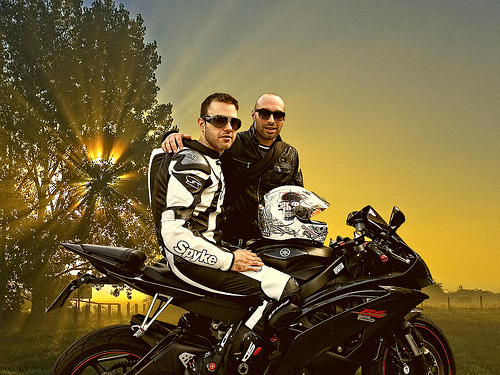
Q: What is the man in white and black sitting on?
A: Motorcycle.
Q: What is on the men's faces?
A: Sunglasses.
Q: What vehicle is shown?
A: Motorcycle.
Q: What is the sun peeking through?
A: Trees.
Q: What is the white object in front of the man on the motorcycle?
A: Helmet.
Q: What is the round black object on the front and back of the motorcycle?
A: Tire.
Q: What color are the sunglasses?
A: Black.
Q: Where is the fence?
A: Behind the men.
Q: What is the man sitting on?
A: A black and red motorcycle.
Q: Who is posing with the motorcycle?
A: Two men.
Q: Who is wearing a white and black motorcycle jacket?
A: The man.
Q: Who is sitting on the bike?
A: A person.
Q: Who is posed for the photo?
A: Two men.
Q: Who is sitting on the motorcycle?
A: One of the men.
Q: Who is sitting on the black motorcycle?
A: The man.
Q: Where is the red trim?
A: On the wheels.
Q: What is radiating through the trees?
A: The sun.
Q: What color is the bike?
A: Black and red.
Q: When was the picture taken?
A: At dusk.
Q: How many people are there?
A: Two.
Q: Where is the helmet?
A: Resting on the bike.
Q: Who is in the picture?
A: Two men.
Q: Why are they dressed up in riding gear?
A: To take a ride.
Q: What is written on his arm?
A: Spyke.